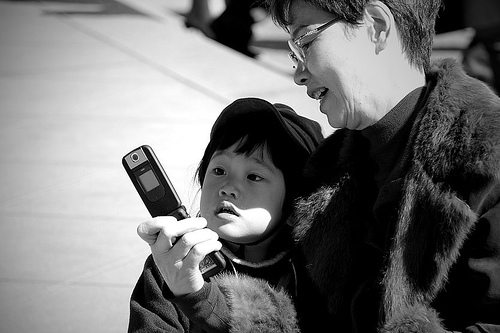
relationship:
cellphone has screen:
[115, 145, 227, 280] [136, 169, 160, 193]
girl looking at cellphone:
[128, 97, 331, 332] [115, 145, 227, 280]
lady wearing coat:
[262, 2, 496, 331] [272, 56, 500, 329]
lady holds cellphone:
[262, 2, 496, 331] [115, 145, 227, 280]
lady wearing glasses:
[262, 2, 496, 331] [286, 8, 381, 69]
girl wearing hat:
[128, 97, 331, 332] [210, 98, 327, 166]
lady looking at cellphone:
[262, 2, 496, 331] [115, 145, 227, 280]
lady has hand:
[262, 2, 496, 331] [137, 214, 224, 295]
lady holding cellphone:
[262, 2, 496, 331] [115, 145, 227, 280]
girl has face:
[128, 97, 331, 332] [199, 117, 298, 241]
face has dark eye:
[199, 117, 298, 241] [211, 165, 226, 178]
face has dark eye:
[199, 117, 298, 241] [247, 173, 262, 184]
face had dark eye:
[199, 117, 298, 241] [211, 165, 226, 178]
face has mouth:
[199, 117, 298, 241] [212, 203, 238, 220]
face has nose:
[199, 117, 298, 241] [218, 173, 242, 199]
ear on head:
[363, 1, 394, 55] [269, 4, 434, 127]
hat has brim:
[210, 98, 327, 166] [212, 99, 293, 147]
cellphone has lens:
[115, 145, 227, 280] [130, 154, 140, 162]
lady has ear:
[262, 2, 496, 331] [363, 1, 394, 55]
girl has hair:
[128, 97, 331, 332] [191, 135, 287, 186]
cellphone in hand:
[115, 145, 227, 280] [137, 214, 224, 295]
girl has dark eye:
[128, 97, 331, 332] [211, 165, 226, 178]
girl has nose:
[128, 97, 331, 332] [218, 173, 242, 199]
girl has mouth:
[128, 97, 331, 332] [212, 203, 238, 220]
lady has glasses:
[262, 2, 496, 331] [286, 8, 381, 69]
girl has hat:
[128, 97, 331, 332] [210, 98, 327, 166]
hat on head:
[210, 98, 327, 166] [199, 117, 298, 241]